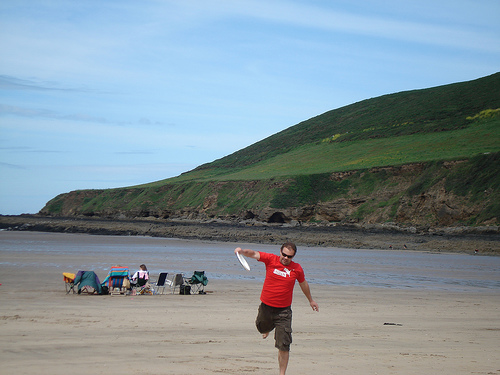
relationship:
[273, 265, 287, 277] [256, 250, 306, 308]
white letters on shirt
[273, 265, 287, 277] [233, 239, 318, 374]
white letters on man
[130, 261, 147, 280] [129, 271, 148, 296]
person sitting in chair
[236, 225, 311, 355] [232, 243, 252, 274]
man holding frisbee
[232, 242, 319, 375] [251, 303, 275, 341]
man has leg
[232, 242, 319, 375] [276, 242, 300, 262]
man has head